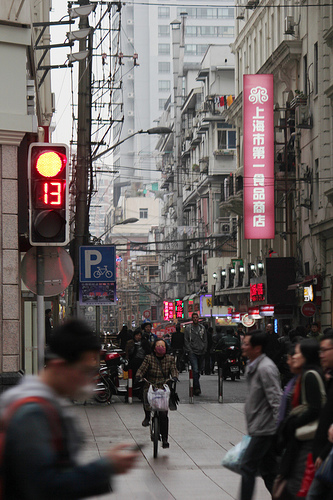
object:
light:
[28, 142, 69, 247]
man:
[134, 340, 180, 460]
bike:
[140, 378, 176, 458]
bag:
[147, 384, 171, 411]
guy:
[0, 319, 145, 499]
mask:
[76, 383, 96, 401]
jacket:
[136, 353, 179, 392]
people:
[0, 318, 333, 500]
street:
[60, 306, 332, 499]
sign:
[244, 73, 275, 240]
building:
[210, 1, 333, 334]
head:
[38, 319, 101, 399]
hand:
[105, 443, 140, 474]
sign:
[79, 245, 117, 284]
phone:
[130, 443, 144, 451]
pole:
[96, 306, 100, 346]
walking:
[35, 179, 64, 208]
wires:
[92, 235, 237, 253]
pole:
[72, 0, 94, 316]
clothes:
[211, 93, 234, 106]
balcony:
[205, 94, 235, 116]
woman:
[271, 339, 328, 499]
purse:
[295, 422, 318, 443]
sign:
[250, 283, 266, 302]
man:
[214, 326, 241, 353]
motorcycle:
[223, 346, 240, 381]